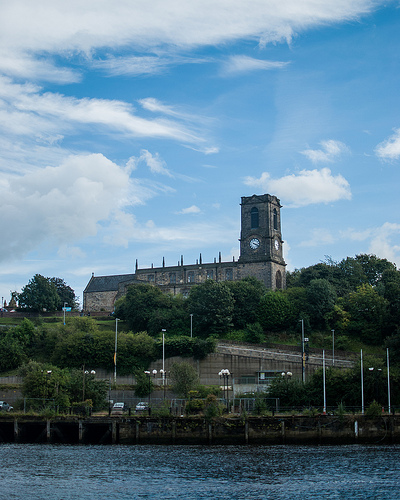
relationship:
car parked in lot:
[110, 397, 131, 414] [24, 369, 317, 413]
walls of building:
[238, 260, 272, 287] [235, 184, 290, 293]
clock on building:
[239, 233, 263, 254] [233, 180, 291, 275]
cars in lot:
[107, 394, 151, 414] [0, 394, 391, 413]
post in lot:
[159, 327, 168, 409] [3, 394, 391, 413]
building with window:
[82, 193, 290, 319] [224, 266, 234, 279]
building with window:
[82, 193, 290, 319] [206, 269, 214, 279]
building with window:
[82, 193, 290, 319] [187, 271, 194, 281]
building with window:
[82, 193, 290, 319] [167, 272, 178, 283]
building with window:
[82, 193, 290, 319] [149, 276, 157, 285]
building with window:
[82, 193, 290, 319] [181, 288, 194, 297]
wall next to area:
[2, 346, 393, 404] [0, 402, 400, 416]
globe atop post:
[226, 371, 231, 374] [220, 373, 231, 415]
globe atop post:
[223, 367, 229, 373] [220, 373, 231, 415]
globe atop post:
[221, 369, 226, 374] [220, 373, 231, 415]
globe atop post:
[218, 371, 223, 375] [220, 373, 231, 415]